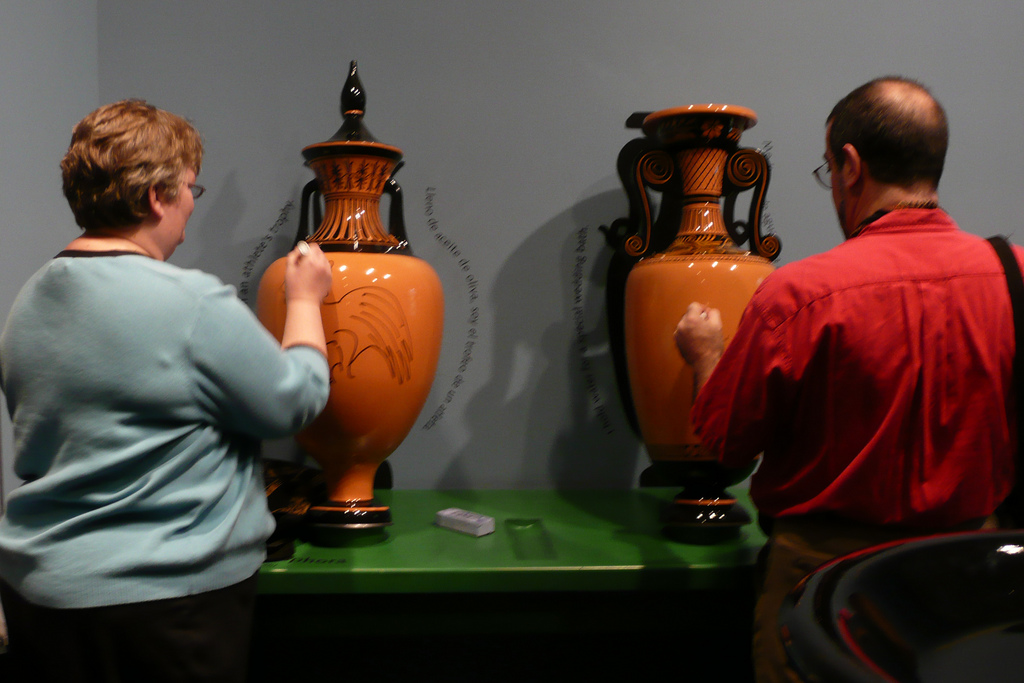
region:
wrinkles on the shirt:
[14, 420, 277, 583]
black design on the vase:
[298, 273, 419, 392]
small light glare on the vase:
[333, 254, 356, 273]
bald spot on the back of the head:
[877, 64, 942, 132]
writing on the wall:
[415, 166, 491, 455]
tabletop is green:
[226, 463, 781, 582]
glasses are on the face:
[156, 164, 210, 204]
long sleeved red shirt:
[659, 206, 1023, 567]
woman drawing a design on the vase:
[19, 29, 487, 652]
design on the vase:
[333, 274, 416, 396]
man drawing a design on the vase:
[598, 25, 1022, 594]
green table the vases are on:
[588, 499, 645, 569]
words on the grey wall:
[416, 173, 486, 448]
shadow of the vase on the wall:
[533, 430, 633, 519]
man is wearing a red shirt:
[775, 56, 1009, 527]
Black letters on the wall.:
[409, 168, 447, 211]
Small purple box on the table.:
[430, 484, 497, 530]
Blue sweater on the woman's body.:
[17, 239, 338, 584]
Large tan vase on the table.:
[269, 16, 447, 563]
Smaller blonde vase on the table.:
[614, 86, 810, 557]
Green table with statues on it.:
[225, 443, 845, 598]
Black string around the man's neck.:
[827, 192, 996, 256]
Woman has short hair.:
[73, 88, 209, 224]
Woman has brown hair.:
[51, 97, 178, 212]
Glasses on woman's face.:
[174, 174, 216, 201]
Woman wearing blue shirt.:
[10, 244, 324, 605]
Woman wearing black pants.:
[21, 571, 287, 657]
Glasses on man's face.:
[808, 151, 838, 184]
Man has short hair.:
[808, 75, 951, 196]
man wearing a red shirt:
[769, 40, 1019, 540]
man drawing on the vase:
[596, 59, 1017, 566]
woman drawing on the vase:
[20, 73, 340, 644]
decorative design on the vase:
[333, 268, 420, 408]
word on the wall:
[416, 165, 484, 457]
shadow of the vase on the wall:
[519, 240, 574, 437]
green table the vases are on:
[566, 525, 650, 565]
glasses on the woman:
[169, 173, 204, 208]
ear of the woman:
[137, 174, 172, 232]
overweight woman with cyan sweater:
[12, 83, 393, 654]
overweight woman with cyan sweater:
[2, 70, 392, 655]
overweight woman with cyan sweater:
[0, 70, 400, 637]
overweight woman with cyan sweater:
[0, 83, 411, 633]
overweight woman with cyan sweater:
[3, 98, 411, 648]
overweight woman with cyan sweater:
[2, 75, 376, 645]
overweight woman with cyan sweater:
[14, 83, 406, 647]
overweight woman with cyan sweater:
[8, 78, 376, 645]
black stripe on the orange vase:
[339, 213, 353, 245]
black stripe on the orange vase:
[329, 194, 342, 243]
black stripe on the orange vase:
[348, 191, 361, 246]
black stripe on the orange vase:
[355, 201, 371, 244]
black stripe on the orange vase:
[318, 197, 334, 240]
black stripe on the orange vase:
[352, 150, 366, 193]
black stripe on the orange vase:
[375, 153, 380, 191]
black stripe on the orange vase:
[320, 155, 331, 195]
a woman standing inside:
[60, 62, 320, 632]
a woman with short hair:
[32, 120, 279, 383]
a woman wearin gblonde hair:
[101, 91, 254, 317]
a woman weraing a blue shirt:
[118, 128, 275, 556]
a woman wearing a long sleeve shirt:
[13, 147, 367, 637]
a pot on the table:
[269, 120, 529, 558]